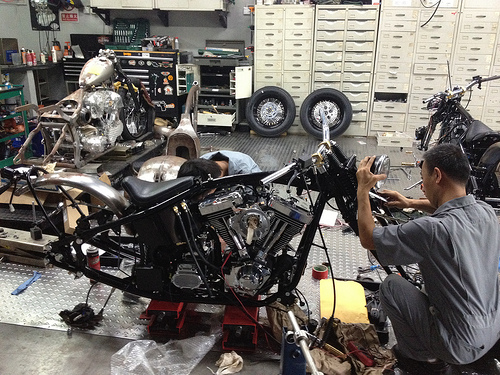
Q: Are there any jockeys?
A: No, there are no jockeys.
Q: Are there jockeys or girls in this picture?
A: No, there are no jockeys or girls.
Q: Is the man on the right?
A: Yes, the man is on the right of the image.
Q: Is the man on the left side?
A: No, the man is on the right of the image.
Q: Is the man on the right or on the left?
A: The man is on the right of the image.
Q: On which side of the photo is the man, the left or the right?
A: The man is on the right of the image.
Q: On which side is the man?
A: The man is on the right of the image.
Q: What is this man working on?
A: The man is working on the motorbike.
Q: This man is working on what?
A: The man is working on the motorbike.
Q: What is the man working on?
A: The man is working on the motorbike.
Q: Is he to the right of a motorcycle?
A: Yes, the man is to the right of a motorcycle.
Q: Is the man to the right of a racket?
A: No, the man is to the right of a motorcycle.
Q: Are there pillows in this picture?
A: No, there are no pillows.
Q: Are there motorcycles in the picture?
A: Yes, there is a motorcycle.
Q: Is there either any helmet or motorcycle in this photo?
A: Yes, there is a motorcycle.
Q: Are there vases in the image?
A: No, there are no vases.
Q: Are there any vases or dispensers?
A: No, there are no vases or dispensers.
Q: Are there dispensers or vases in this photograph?
A: No, there are no vases or dispensers.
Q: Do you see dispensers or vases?
A: No, there are no vases or dispensers.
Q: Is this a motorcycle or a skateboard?
A: This is a motorcycle.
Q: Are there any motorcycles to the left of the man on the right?
A: Yes, there is a motorcycle to the left of the man.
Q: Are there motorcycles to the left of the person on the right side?
A: Yes, there is a motorcycle to the left of the man.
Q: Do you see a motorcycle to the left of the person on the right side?
A: Yes, there is a motorcycle to the left of the man.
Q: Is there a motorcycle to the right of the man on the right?
A: No, the motorcycle is to the left of the man.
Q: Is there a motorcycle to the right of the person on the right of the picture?
A: No, the motorcycle is to the left of the man.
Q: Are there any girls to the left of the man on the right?
A: No, there is a motorcycle to the left of the man.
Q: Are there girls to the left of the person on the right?
A: No, there is a motorcycle to the left of the man.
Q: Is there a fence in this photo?
A: No, there are no fences.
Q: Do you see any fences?
A: No, there are no fences.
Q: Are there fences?
A: No, there are no fences.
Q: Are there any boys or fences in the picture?
A: No, there are no fences or boys.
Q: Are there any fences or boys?
A: No, there are no fences or boys.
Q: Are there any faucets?
A: No, there are no faucets.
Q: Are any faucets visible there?
A: No, there are no faucets.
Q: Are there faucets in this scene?
A: No, there are no faucets.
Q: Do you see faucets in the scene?
A: No, there are no faucets.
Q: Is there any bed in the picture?
A: No, there are no beds.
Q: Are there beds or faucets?
A: No, there are no beds or faucets.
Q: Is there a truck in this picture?
A: No, there are no trucks.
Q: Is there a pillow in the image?
A: No, there are no pillows.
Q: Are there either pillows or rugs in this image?
A: No, there are no pillows or rugs.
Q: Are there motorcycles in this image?
A: Yes, there is a motorcycle.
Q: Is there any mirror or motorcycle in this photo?
A: Yes, there is a motorcycle.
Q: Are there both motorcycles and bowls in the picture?
A: No, there is a motorcycle but no bowls.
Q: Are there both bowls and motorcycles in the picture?
A: No, there is a motorcycle but no bowls.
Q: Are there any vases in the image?
A: No, there are no vases.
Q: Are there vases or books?
A: No, there are no vases or books.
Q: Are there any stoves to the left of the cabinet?
A: No, there is a motorcycle to the left of the cabinet.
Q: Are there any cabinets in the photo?
A: Yes, there is a cabinet.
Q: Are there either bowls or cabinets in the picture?
A: Yes, there is a cabinet.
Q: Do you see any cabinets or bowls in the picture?
A: Yes, there is a cabinet.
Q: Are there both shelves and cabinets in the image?
A: Yes, there are both a cabinet and a shelf.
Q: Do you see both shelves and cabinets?
A: Yes, there are both a cabinet and a shelf.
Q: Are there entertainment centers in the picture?
A: No, there are no entertainment centers.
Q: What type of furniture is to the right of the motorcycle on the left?
A: The piece of furniture is a cabinet.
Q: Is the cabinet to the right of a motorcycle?
A: Yes, the cabinet is to the right of a motorcycle.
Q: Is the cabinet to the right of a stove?
A: No, the cabinet is to the right of a motorcycle.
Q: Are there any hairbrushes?
A: No, there are no hairbrushes.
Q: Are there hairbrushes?
A: No, there are no hairbrushes.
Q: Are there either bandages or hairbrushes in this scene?
A: No, there are no hairbrushes or bandages.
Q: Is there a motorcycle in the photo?
A: Yes, there is a motorcycle.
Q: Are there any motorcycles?
A: Yes, there is a motorcycle.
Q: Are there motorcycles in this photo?
A: Yes, there is a motorcycle.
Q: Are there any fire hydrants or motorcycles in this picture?
A: Yes, there is a motorcycle.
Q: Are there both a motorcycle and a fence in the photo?
A: No, there is a motorcycle but no fences.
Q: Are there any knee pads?
A: No, there are no knee pads.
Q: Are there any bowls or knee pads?
A: No, there are no knee pads or bowls.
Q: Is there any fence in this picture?
A: No, there are no fences.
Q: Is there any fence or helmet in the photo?
A: No, there are no fences or helmets.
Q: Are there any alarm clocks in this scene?
A: No, there are no alarm clocks.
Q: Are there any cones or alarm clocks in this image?
A: No, there are no alarm clocks or cones.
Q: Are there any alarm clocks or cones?
A: No, there are no alarm clocks or cones.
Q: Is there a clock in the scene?
A: No, there are no clocks.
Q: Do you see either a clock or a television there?
A: No, there are no clocks or televisions.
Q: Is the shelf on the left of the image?
A: Yes, the shelf is on the left of the image.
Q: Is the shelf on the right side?
A: No, the shelf is on the left of the image.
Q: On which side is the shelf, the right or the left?
A: The shelf is on the left of the image.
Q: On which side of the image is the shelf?
A: The shelf is on the left of the image.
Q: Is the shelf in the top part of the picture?
A: Yes, the shelf is in the top of the image.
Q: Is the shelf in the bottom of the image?
A: No, the shelf is in the top of the image.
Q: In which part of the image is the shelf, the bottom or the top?
A: The shelf is in the top of the image.